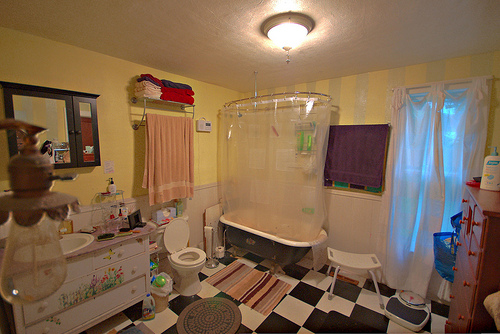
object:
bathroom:
[0, 0, 497, 332]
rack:
[129, 96, 196, 129]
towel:
[144, 111, 196, 206]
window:
[373, 109, 463, 194]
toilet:
[163, 217, 208, 296]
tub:
[218, 207, 328, 274]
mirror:
[9, 92, 72, 165]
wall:
[3, 48, 142, 203]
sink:
[19, 233, 93, 256]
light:
[266, 23, 307, 52]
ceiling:
[173, 8, 363, 79]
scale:
[383, 296, 432, 332]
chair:
[325, 247, 387, 310]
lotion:
[97, 228, 140, 241]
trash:
[140, 271, 181, 316]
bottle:
[107, 177, 117, 193]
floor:
[264, 290, 381, 334]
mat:
[205, 258, 292, 316]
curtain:
[219, 98, 335, 242]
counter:
[91, 222, 158, 312]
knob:
[132, 267, 138, 273]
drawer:
[95, 234, 149, 269]